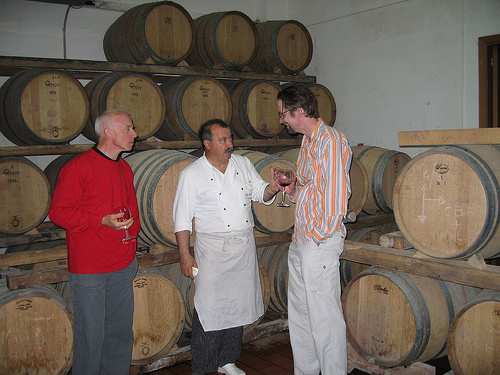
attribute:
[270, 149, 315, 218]
glass — wine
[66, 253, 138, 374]
pant — dark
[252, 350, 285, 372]
floor — smooth, red, brick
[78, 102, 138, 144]
hair — white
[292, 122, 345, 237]
shirt — striped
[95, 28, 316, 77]
barrels — stacked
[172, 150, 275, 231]
shirt — white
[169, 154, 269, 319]
clothes — white, work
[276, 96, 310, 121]
glasses — eye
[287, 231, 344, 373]
pants — white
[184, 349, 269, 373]
shoes — white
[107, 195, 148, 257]
glass — tall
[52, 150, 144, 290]
shirt — red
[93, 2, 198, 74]
drum — many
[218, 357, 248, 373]
shoe — white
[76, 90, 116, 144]
hair — gray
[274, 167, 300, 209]
glass — tall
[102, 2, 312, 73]
barrels — brown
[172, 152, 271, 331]
clothes — white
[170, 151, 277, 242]
shirt — white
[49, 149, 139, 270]
shirt — red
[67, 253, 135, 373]
pants — grey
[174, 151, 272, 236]
shirt — white